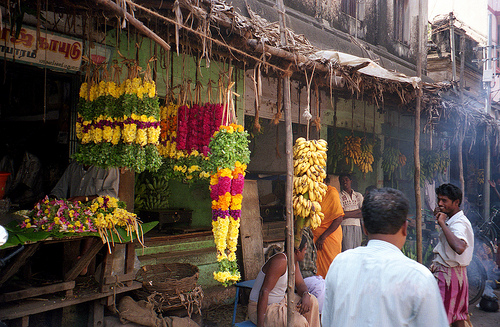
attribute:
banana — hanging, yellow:
[283, 128, 329, 231]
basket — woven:
[129, 252, 206, 314]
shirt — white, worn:
[315, 245, 445, 325]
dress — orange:
[315, 181, 344, 275]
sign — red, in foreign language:
[0, 24, 83, 69]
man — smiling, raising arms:
[420, 180, 472, 325]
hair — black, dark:
[358, 185, 408, 230]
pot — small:
[479, 296, 499, 310]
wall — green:
[116, 36, 224, 108]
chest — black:
[272, 264, 295, 292]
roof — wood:
[144, 2, 466, 123]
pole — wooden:
[284, 74, 295, 318]